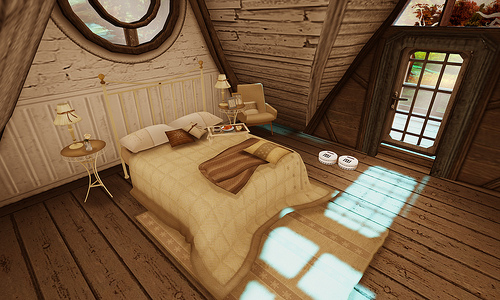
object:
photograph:
[0, 0, 500, 300]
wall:
[203, 0, 398, 126]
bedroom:
[0, 0, 499, 298]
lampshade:
[52, 102, 82, 126]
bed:
[117, 109, 311, 250]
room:
[0, 0, 500, 300]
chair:
[234, 81, 278, 136]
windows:
[389, 108, 410, 133]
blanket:
[197, 135, 273, 196]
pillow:
[242, 138, 296, 165]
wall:
[0, 0, 252, 209]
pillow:
[181, 120, 208, 139]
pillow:
[164, 128, 197, 148]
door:
[360, 30, 491, 177]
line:
[8, 211, 46, 300]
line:
[40, 201, 103, 299]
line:
[66, 190, 156, 300]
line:
[94, 179, 211, 299]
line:
[116, 172, 134, 187]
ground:
[0, 120, 499, 300]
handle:
[389, 90, 409, 111]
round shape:
[51, 0, 188, 64]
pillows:
[168, 111, 224, 130]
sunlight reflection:
[234, 162, 431, 300]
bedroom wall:
[0, 0, 238, 204]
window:
[53, 0, 183, 57]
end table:
[59, 137, 116, 203]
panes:
[410, 87, 437, 117]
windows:
[435, 61, 468, 92]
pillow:
[118, 123, 178, 154]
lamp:
[52, 101, 85, 150]